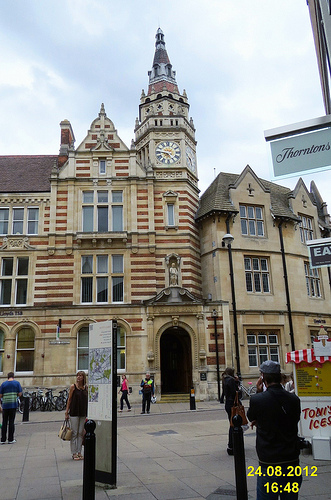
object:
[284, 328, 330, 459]
stand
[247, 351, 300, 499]
man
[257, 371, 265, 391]
phone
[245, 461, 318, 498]
stamp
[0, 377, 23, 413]
shirt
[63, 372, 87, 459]
woman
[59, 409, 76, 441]
purse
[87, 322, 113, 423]
map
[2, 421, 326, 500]
sidewalk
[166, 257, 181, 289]
statue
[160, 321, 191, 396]
door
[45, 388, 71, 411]
bike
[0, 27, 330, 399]
building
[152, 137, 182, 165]
clock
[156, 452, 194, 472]
stone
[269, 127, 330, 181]
sign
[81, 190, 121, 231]
window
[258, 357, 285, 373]
hat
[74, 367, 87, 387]
head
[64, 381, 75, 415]
arm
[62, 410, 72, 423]
hand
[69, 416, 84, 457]
pants